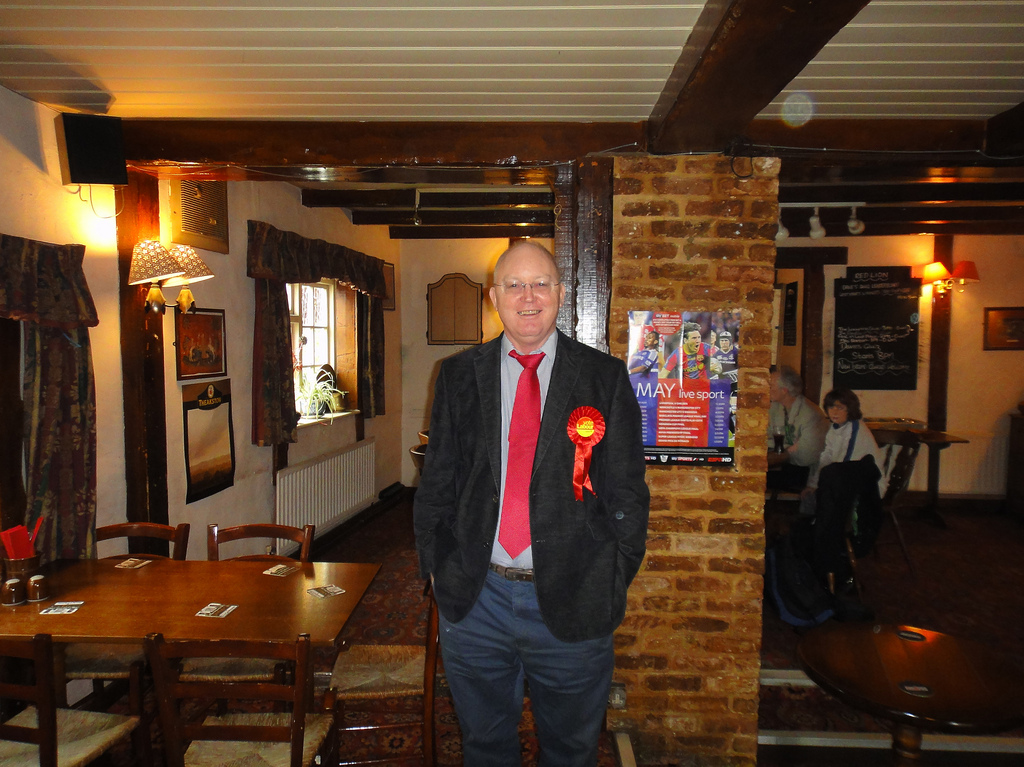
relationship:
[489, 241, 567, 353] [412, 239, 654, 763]
head on man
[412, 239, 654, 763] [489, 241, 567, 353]
man with a head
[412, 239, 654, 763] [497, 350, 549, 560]
man wearing tie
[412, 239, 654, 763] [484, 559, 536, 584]
man wearing belt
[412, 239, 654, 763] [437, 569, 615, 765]
man wearing pants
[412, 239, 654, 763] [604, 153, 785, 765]
man next to wall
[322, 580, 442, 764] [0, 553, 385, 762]
chair next to table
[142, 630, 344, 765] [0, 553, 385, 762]
chair next to table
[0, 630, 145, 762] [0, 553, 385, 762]
chair next to table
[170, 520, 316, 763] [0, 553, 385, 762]
chair next to table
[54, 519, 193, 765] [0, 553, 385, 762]
chair next to table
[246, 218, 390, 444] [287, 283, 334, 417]
drapes covering window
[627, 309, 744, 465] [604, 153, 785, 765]
poster on wall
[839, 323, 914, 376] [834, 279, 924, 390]
writing on board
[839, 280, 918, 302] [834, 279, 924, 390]
writing on board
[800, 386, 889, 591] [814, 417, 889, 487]
woman wearing shirt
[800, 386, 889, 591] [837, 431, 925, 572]
woman sitting on chair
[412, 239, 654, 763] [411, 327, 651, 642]
man wearing jacket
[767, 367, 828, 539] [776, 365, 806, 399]
man with hair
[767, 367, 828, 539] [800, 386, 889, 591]
man next to woman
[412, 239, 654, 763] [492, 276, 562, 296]
man wearing glasses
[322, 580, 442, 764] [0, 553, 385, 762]
chair around table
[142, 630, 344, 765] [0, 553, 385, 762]
chair around table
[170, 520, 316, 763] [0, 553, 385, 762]
chair around table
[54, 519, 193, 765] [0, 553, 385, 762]
chair around table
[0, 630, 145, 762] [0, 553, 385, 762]
chair around table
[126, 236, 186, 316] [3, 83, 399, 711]
light fixture attached to wall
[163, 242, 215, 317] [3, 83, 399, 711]
light fixture attached to wall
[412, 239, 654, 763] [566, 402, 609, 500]
man wearing ribbon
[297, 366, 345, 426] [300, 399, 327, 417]
plant in pot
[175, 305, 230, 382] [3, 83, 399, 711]
picture on wall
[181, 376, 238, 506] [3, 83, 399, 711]
picture on wall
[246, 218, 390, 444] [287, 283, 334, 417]
drapes surrounding window